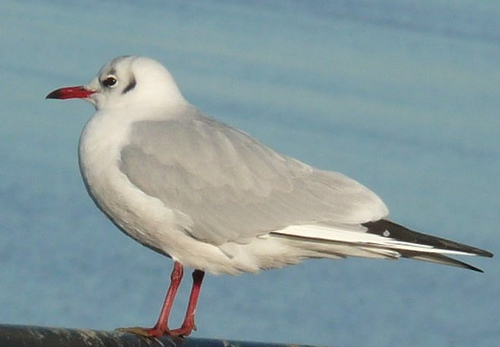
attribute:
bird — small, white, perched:
[41, 46, 470, 321]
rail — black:
[12, 318, 136, 344]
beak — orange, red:
[31, 71, 88, 107]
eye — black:
[95, 73, 122, 97]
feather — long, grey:
[299, 222, 407, 240]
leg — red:
[144, 258, 178, 328]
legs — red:
[148, 265, 204, 332]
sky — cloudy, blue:
[215, 22, 406, 98]